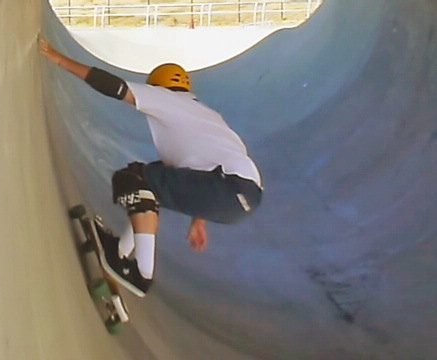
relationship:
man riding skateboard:
[36, 36, 261, 299] [72, 203, 129, 332]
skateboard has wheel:
[72, 203, 129, 332] [68, 202, 86, 223]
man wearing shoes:
[36, 36, 261, 299] [89, 214, 155, 303]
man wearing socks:
[36, 36, 261, 299] [115, 220, 156, 282]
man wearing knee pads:
[36, 36, 261, 299] [112, 160, 160, 217]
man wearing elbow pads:
[36, 36, 261, 299] [84, 65, 129, 101]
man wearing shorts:
[36, 36, 261, 299] [144, 160, 264, 223]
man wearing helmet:
[36, 36, 261, 299] [146, 62, 191, 92]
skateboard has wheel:
[72, 203, 129, 332] [88, 279, 113, 302]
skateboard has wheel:
[72, 203, 129, 332] [106, 315, 127, 339]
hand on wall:
[32, 30, 60, 63] [0, 1, 116, 359]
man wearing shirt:
[36, 36, 261, 299] [127, 82, 261, 190]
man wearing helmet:
[127, 81, 262, 185] [146, 62, 191, 92]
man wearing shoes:
[127, 81, 262, 185] [89, 214, 155, 303]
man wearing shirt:
[127, 81, 262, 185] [127, 82, 261, 190]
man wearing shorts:
[127, 81, 262, 185] [144, 160, 264, 223]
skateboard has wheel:
[72, 203, 129, 332] [80, 238, 97, 257]